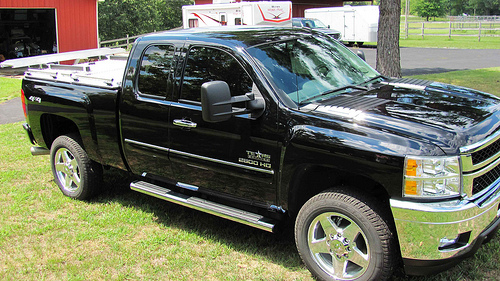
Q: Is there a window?
A: Yes, there is a window.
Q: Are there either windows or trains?
A: Yes, there is a window.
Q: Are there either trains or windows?
A: Yes, there is a window.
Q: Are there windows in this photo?
A: Yes, there is a window.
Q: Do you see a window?
A: Yes, there is a window.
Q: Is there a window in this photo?
A: Yes, there is a window.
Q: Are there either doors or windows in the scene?
A: Yes, there is a window.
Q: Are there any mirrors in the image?
A: Yes, there is a mirror.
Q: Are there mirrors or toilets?
A: Yes, there is a mirror.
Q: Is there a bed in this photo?
A: Yes, there is a bed.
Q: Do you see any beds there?
A: Yes, there is a bed.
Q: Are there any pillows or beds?
A: Yes, there is a bed.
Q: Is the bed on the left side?
A: Yes, the bed is on the left of the image.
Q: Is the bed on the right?
A: No, the bed is on the left of the image.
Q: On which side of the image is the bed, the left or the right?
A: The bed is on the left of the image.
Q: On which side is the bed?
A: The bed is on the left of the image.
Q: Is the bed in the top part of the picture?
A: Yes, the bed is in the top of the image.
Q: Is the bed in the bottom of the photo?
A: No, the bed is in the top of the image.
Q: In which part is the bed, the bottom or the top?
A: The bed is in the top of the image.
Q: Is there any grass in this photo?
A: Yes, there is grass.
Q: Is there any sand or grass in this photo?
A: Yes, there is grass.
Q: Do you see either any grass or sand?
A: Yes, there is grass.